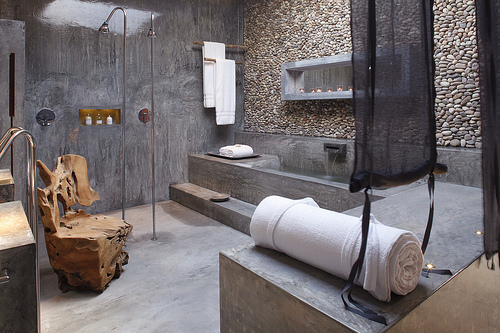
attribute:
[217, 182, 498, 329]
cupboard — silver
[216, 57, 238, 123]
towel — hanging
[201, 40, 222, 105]
towel — hanging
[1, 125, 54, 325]
railing — gray , metal 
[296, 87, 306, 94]
candle — lit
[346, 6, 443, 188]
cloth — dark, see-through, hanging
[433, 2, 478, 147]
rocks — river, wall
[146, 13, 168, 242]
shower head — silver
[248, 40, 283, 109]
wall — rock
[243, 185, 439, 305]
white towel — rolled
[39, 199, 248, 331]
gray floor — light grey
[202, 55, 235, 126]
towel — hanging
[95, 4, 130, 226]
shower head — Tall, gray, metal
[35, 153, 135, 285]
chair — sculpted, wood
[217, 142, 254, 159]
towel — folded, white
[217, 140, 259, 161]
towel — folded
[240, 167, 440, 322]
mat — rolled-up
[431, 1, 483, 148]
wall — gray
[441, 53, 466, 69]
pebbles — light